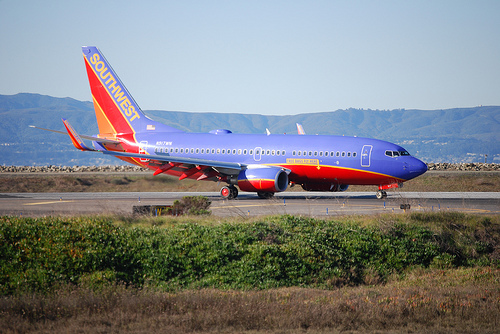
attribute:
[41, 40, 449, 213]
airplane — blue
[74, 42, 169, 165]
stripes —  yellow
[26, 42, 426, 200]
plane — blue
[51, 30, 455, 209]
plane — big, multicolored, blue, red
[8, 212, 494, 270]
green bushes — long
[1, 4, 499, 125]
sky — smoggy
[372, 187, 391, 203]
plane wheels — black, red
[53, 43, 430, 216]
airplane — blue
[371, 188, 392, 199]
black wheels — red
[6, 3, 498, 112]
blue sky — clear, cloudless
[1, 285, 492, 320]
dried grass — brown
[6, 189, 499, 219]
black road — concrete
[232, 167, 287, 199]
airplane engine —  blue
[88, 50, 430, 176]
plane —  blue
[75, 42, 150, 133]
vertical stabilizer —  blue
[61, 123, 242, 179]
plane wing — blue, red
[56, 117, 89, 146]
wing — red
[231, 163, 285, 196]
plane engine — blue, red